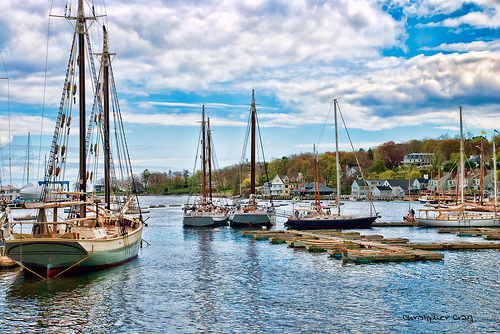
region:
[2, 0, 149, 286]
Sailboat on the water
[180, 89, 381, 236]
Three boats in the harbor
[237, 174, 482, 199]
Houses along the edge of the shore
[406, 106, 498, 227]
Boat docked at the harbor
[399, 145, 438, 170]
White house on a hill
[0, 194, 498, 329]
Calm water in the harbor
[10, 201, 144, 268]
A boat floating in a harbor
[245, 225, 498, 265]
A wooden dock stretching into the water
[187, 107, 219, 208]
A tall mast on a boat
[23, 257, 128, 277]
Painted red bottom of a boat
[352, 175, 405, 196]
Buildings on the shore of a lake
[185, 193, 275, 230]
Two boats floating in the water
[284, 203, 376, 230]
A dark colored boat near a dock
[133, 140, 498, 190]
A tree covered hill beside a lake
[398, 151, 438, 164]
A house halfway up a hill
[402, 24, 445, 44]
A patch of blue sky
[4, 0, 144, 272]
this is a boat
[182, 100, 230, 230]
this is a boat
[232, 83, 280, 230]
this is a boat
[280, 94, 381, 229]
this is a boat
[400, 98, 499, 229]
this is a boat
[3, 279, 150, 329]
this is a body of water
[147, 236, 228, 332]
this is a body of water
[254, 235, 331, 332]
this is a body of water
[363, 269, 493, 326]
this is a body of water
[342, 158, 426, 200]
this is a building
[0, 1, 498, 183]
white puffy clouds in blue sky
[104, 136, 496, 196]
tree tops and houses on horizon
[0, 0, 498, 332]
houses overlooking boats in harbor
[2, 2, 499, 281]
boat masts with no sails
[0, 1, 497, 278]
anchored boats in harbor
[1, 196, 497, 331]
calm surface of harbor water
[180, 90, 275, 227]
sterns of two sailboats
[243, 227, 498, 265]
floating dock on water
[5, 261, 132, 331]
reflection on water surface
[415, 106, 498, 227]
sailboat with white body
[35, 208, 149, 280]
boat in water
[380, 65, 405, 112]
white clouds in blue sky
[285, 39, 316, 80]
white clouds in blue sky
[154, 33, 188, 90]
white clouds in blue sky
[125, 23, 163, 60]
white clouds in blue sky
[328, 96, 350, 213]
one mast on a boat